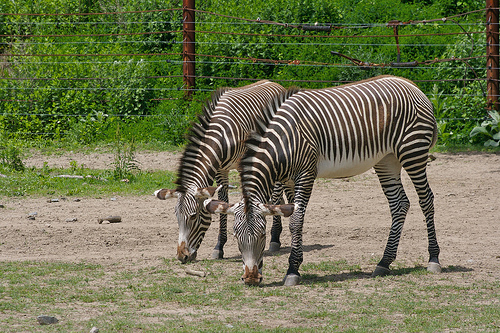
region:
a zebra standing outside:
[215, 77, 458, 331]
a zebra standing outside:
[147, 47, 264, 257]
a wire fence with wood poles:
[72, 8, 497, 176]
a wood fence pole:
[169, 8, 254, 145]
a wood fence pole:
[464, 10, 497, 69]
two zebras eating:
[127, 44, 462, 296]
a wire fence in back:
[14, 18, 498, 72]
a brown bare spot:
[0, 187, 155, 269]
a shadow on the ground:
[271, 249, 477, 299]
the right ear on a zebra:
[141, 178, 183, 206]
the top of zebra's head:
[196, 198, 310, 225]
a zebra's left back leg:
[405, 132, 446, 292]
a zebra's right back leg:
[365, 165, 410, 291]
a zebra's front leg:
[283, 166, 323, 296]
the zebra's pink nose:
[238, 258, 269, 290]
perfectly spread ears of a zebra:
[202, 197, 299, 222]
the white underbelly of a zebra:
[314, 158, 384, 180]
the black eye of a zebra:
[188, 213, 196, 218]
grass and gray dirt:
[3, 140, 495, 328]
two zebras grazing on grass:
[154, 72, 440, 285]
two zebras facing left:
[153, 70, 444, 287]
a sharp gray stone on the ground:
[37, 311, 59, 326]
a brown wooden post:
[180, 2, 192, 91]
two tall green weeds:
[111, 138, 136, 179]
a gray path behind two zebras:
[0, 145, 176, 176]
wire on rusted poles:
[2, 1, 497, 118]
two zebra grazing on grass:
[156, 75, 438, 285]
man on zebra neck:
[239, 93, 288, 203]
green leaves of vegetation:
[3, 3, 495, 137]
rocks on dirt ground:
[1, 194, 123, 226]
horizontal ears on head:
[207, 201, 293, 283]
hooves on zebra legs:
[280, 261, 441, 288]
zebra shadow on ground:
[261, 262, 470, 289]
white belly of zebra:
[318, 152, 382, 177]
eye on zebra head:
[188, 211, 200, 222]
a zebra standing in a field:
[247, 65, 497, 305]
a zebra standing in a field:
[175, 63, 275, 250]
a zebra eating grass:
[257, 79, 456, 330]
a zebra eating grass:
[149, 55, 274, 237]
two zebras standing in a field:
[168, 18, 464, 332]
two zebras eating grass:
[146, 8, 474, 328]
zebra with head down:
[215, 74, 420, 330]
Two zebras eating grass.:
[152, 78, 441, 285]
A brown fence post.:
[181, 0, 194, 95]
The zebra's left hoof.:
[282, 271, 299, 286]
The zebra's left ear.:
[262, 202, 295, 217]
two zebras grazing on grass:
[144, 69, 449, 292]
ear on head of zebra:
[150, 183, 187, 203]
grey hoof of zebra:
[276, 270, 303, 289]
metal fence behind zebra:
[3, 2, 498, 142]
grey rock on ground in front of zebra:
[29, 310, 64, 329]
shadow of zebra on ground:
[248, 259, 480, 291]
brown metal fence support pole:
[176, 0, 202, 108]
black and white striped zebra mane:
[236, 88, 300, 229]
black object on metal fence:
[292, 19, 336, 37]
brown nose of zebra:
[237, 264, 264, 286]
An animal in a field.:
[229, 68, 446, 272]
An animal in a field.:
[147, 69, 264, 284]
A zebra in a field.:
[148, 80, 283, 266]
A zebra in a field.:
[231, 70, 438, 300]